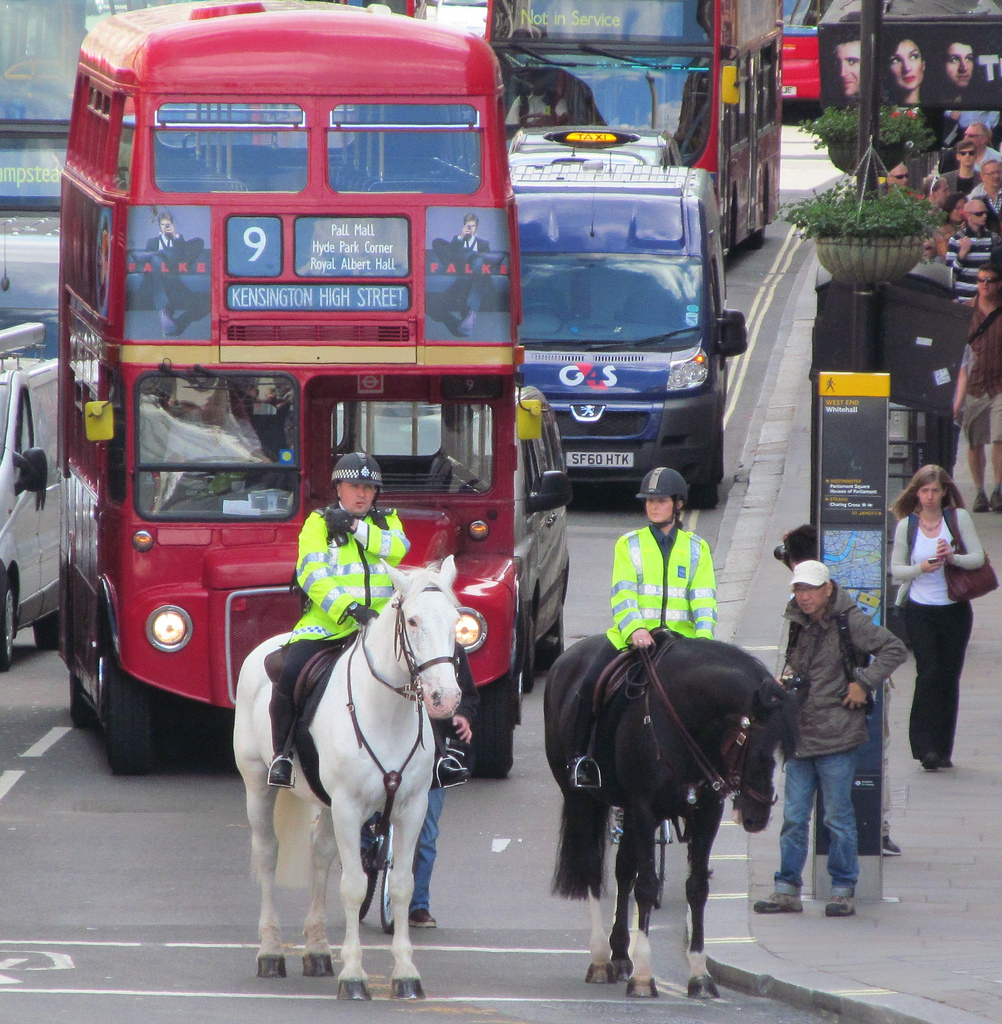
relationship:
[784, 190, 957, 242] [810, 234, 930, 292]
plant in basket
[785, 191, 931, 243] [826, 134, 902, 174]
plant in basket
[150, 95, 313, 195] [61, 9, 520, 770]
window on automobiles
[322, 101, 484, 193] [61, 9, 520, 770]
window on automobiles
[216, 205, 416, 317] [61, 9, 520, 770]
sign on automobiles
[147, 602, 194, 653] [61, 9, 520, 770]
headlight on automobiles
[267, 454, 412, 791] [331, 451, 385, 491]
man wearing helmet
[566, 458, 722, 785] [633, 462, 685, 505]
woman wearing helmet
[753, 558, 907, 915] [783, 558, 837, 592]
man wearing hat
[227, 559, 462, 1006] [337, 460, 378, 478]
horse used department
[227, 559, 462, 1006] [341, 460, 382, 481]
horse used department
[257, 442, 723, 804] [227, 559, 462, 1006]
police mounted horse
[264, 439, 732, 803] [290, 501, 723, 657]
officers wear vests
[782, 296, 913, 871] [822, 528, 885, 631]
posts with maps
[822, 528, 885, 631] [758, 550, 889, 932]
maps for visitors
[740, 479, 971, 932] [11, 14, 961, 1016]
commuters walk city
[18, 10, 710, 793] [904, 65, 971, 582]
automobiles use people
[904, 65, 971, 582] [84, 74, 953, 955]
people commute city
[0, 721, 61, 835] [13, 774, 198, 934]
lines across road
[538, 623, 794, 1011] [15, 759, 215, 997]
horse on street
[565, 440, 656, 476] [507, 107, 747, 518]
plate of car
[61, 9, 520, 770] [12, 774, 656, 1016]
automobiles on road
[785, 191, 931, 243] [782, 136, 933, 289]
plant in pot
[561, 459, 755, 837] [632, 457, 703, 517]
person wearing helmet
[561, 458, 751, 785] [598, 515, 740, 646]
person wearing coat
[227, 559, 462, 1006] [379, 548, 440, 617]
horse has mane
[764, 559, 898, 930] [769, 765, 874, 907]
person wearing jeans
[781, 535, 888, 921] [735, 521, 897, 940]
man on corner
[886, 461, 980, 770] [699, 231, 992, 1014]
woman walking down sidewalk